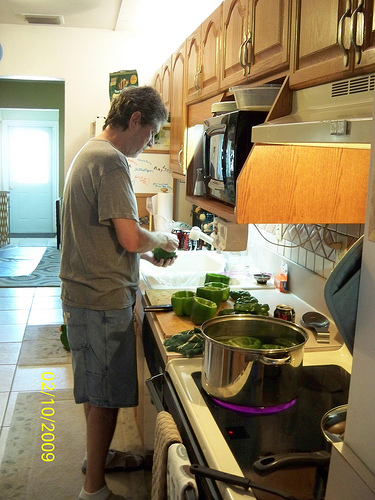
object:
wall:
[1, 23, 145, 85]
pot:
[194, 310, 311, 406]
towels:
[165, 441, 198, 499]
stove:
[188, 363, 355, 499]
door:
[3, 74, 67, 238]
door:
[3, 107, 62, 235]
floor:
[2, 239, 64, 499]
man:
[59, 85, 181, 499]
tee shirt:
[59, 137, 142, 311]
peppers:
[192, 295, 219, 322]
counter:
[138, 259, 340, 370]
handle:
[249, 447, 330, 477]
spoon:
[301, 309, 333, 344]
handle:
[144, 368, 206, 496]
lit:
[206, 395, 300, 418]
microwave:
[197, 110, 263, 208]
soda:
[274, 305, 296, 320]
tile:
[311, 229, 321, 241]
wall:
[248, 223, 363, 330]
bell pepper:
[156, 248, 174, 263]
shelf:
[185, 196, 238, 222]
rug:
[15, 324, 74, 368]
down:
[136, 123, 184, 268]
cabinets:
[154, 0, 373, 184]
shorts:
[62, 301, 139, 408]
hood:
[248, 72, 374, 142]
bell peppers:
[171, 289, 196, 316]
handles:
[238, 31, 255, 79]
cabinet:
[220, 0, 292, 91]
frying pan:
[251, 405, 349, 477]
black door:
[205, 122, 227, 199]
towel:
[150, 409, 183, 499]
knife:
[142, 302, 174, 314]